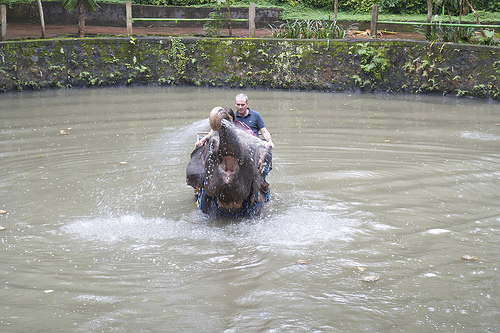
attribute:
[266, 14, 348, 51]
plant —  green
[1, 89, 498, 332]
water — BROWN, dark, grey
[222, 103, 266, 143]
shirt — blue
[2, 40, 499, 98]
dirt — grey, dark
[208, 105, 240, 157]
trunk — grey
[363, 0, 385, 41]
tree —  thin,  brown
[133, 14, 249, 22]
rope — green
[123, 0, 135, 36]
pole — wooden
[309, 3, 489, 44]
grass —  green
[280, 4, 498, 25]
grass — green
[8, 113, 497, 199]
ripples — round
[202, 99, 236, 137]
trunk —  curled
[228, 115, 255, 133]
shirt — red colored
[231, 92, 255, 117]
head — bald